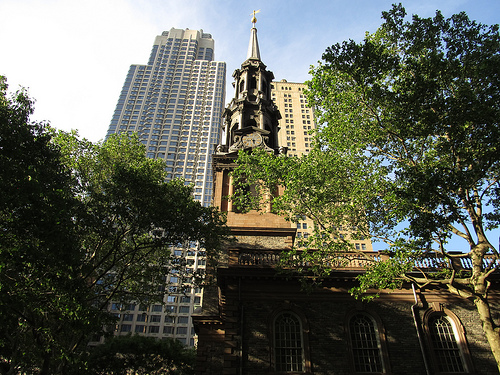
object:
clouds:
[273, 34, 336, 66]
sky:
[400, 0, 500, 15]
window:
[426, 308, 466, 373]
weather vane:
[249, 8, 261, 29]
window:
[348, 313, 383, 375]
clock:
[241, 130, 262, 147]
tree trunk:
[451, 269, 498, 322]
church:
[224, 239, 491, 370]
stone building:
[243, 318, 291, 365]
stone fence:
[237, 248, 497, 271]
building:
[92, 283, 212, 361]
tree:
[229, 0, 500, 375]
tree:
[0, 73, 240, 375]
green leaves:
[0, 252, 52, 293]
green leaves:
[103, 184, 160, 211]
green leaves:
[32, 301, 62, 351]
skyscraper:
[75, 26, 229, 374]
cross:
[249, 8, 262, 21]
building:
[95, 29, 220, 195]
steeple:
[240, 9, 267, 72]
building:
[197, 53, 322, 164]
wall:
[144, 99, 201, 131]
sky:
[279, 7, 329, 57]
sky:
[310, 8, 349, 35]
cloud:
[1, 0, 126, 72]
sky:
[0, 1, 85, 51]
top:
[247, 9, 261, 18]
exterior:
[378, 290, 413, 305]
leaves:
[324, 73, 360, 102]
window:
[272, 311, 304, 373]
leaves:
[324, 124, 360, 145]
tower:
[213, 13, 297, 247]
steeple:
[247, 27, 261, 59]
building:
[273, 78, 371, 254]